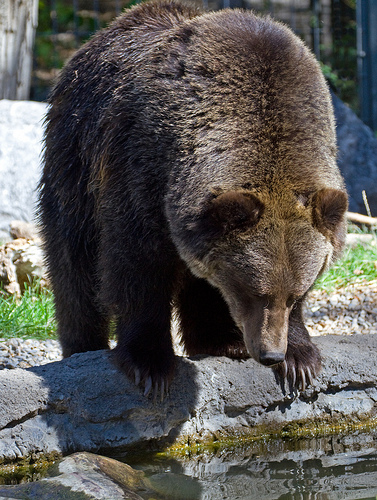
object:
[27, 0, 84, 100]
people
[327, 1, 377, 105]
outdoors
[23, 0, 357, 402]
bear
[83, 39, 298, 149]
fur